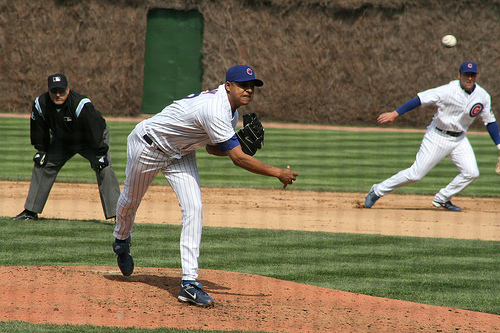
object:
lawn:
[0, 216, 497, 318]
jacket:
[30, 90, 108, 156]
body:
[110, 92, 298, 306]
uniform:
[111, 84, 240, 281]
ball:
[442, 35, 458, 48]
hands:
[93, 154, 108, 173]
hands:
[32, 150, 47, 166]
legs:
[87, 158, 122, 211]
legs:
[22, 157, 73, 206]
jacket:
[144, 84, 241, 160]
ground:
[474, 173, 484, 184]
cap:
[226, 64, 264, 87]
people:
[10, 61, 500, 307]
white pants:
[111, 120, 201, 280]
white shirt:
[416, 79, 496, 132]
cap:
[48, 73, 68, 90]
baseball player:
[365, 62, 500, 212]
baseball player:
[112, 64, 298, 306]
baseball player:
[7, 74, 133, 234]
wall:
[0, 0, 500, 134]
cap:
[460, 61, 479, 73]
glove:
[234, 112, 265, 156]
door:
[140, 7, 204, 113]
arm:
[198, 113, 276, 177]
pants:
[373, 126, 479, 204]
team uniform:
[372, 80, 498, 204]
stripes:
[133, 151, 160, 189]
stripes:
[74, 97, 91, 117]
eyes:
[239, 84, 247, 87]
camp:
[0, 0, 500, 130]